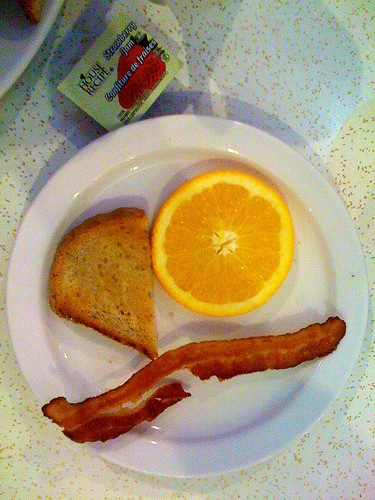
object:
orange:
[147, 167, 295, 316]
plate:
[6, 113, 369, 479]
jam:
[56, 10, 182, 134]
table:
[0, 1, 374, 500]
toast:
[49, 207, 158, 358]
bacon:
[42, 316, 347, 441]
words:
[78, 63, 108, 95]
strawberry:
[117, 44, 166, 110]